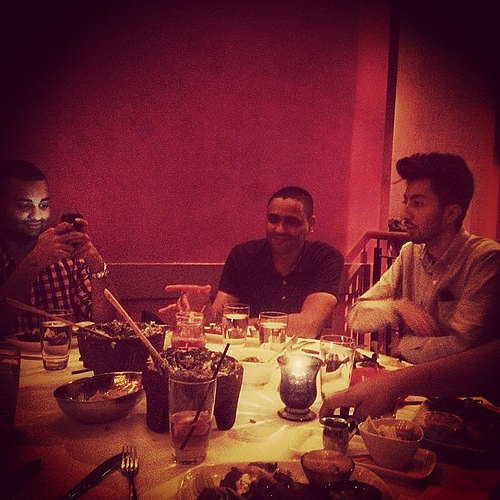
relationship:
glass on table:
[166, 372, 218, 466] [0, 317, 497, 498]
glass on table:
[258, 310, 288, 345] [0, 317, 497, 498]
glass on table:
[38, 318, 74, 371] [0, 317, 497, 498]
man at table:
[345, 147, 495, 374] [0, 317, 497, 498]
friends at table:
[0, 155, 124, 339] [0, 317, 497, 498]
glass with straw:
[166, 372, 218, 466] [179, 340, 230, 450]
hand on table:
[298, 362, 392, 431] [5, 335, 473, 495]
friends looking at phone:
[0, 155, 124, 339] [59, 204, 84, 257]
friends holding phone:
[0, 155, 124, 339] [55, 206, 91, 251]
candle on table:
[277, 352, 323, 421] [0, 317, 497, 498]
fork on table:
[62, 448, 132, 500] [2, 309, 449, 499]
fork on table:
[117, 440, 141, 499] [2, 309, 449, 499]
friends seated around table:
[0, 155, 124, 339] [24, 304, 456, 496]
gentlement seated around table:
[152, 171, 351, 337] [24, 304, 456, 496]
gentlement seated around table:
[330, 145, 478, 374] [24, 304, 456, 496]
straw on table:
[221, 338, 229, 380] [0, 317, 497, 498]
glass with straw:
[168, 375, 216, 462] [221, 338, 229, 380]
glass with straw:
[166, 372, 218, 466] [221, 338, 229, 380]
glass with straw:
[38, 318, 70, 366] [221, 338, 229, 380]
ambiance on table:
[269, 348, 322, 423] [2, 309, 449, 499]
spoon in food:
[101, 282, 191, 379] [132, 339, 242, 434]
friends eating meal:
[0, 153, 498, 424] [0, 320, 497, 498]